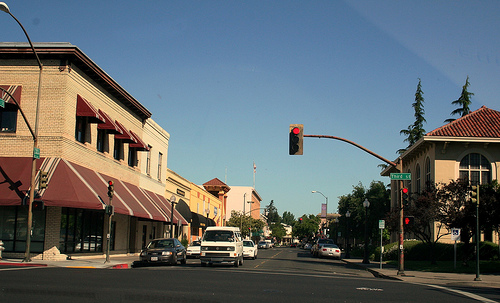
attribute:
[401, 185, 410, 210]
traffic light — red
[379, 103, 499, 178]
roof — brown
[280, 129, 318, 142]
light — red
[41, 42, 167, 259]
building — brick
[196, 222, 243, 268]
van — white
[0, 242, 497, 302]
street — black, asphalt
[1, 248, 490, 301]
streets — concrete, grey, dark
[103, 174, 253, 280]
cars — parked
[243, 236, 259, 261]
car — white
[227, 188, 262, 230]
building — square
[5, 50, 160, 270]
building — Multistory, bricks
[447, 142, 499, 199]
window — arched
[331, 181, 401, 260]
trees — green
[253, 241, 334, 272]
lines — white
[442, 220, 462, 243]
sign — blue, white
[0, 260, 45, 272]
curb — red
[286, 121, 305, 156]
street light — metal, red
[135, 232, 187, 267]
car — black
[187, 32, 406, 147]
sky — clear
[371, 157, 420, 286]
street sign — green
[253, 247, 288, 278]
lines — yellow, dotted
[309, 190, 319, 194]
street light — tall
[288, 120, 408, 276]
stop light — red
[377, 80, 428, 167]
tree — tall, green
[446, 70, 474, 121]
tree — tall, green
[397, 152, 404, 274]
pole — metal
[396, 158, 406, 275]
pole — tall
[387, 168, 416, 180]
street sign — green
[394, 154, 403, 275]
pole — metal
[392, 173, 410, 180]
letters — white